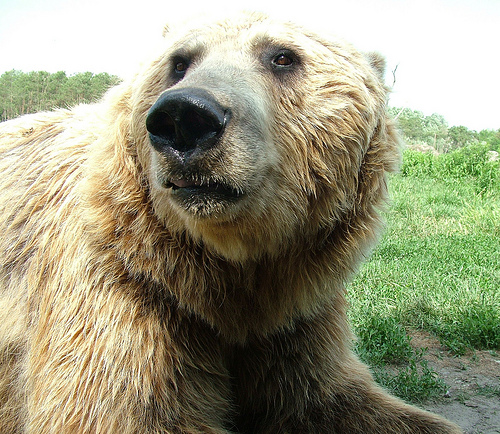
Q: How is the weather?
A: It is clear.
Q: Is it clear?
A: Yes, it is clear.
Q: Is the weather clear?
A: Yes, it is clear.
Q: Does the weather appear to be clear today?
A: Yes, it is clear.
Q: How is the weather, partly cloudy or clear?
A: It is clear.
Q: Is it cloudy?
A: No, it is clear.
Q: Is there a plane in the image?
A: No, there are no airplanes.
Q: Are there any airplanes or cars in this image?
A: No, there are no airplanes or cars.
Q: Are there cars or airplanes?
A: No, there are no airplanes or cars.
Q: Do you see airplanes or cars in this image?
A: No, there are no airplanes or cars.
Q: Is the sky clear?
A: Yes, the sky is clear.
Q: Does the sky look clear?
A: Yes, the sky is clear.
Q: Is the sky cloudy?
A: No, the sky is clear.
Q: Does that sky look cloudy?
A: No, the sky is clear.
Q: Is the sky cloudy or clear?
A: The sky is clear.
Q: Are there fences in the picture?
A: No, there are no fences.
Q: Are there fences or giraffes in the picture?
A: No, there are no fences or giraffes.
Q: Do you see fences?
A: No, there are no fences.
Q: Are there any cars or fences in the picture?
A: No, there are no fences or cars.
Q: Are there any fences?
A: No, there are no fences.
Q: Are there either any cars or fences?
A: No, there are no fences or cars.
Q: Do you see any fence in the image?
A: No, there are no fences.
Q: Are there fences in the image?
A: No, there are no fences.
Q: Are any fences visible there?
A: No, there are no fences.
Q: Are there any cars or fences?
A: No, there are no fences or cars.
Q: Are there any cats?
A: No, there are no cats.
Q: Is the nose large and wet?
A: Yes, the nose is large and wet.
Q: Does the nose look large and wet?
A: Yes, the nose is large and wet.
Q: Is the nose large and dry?
A: No, the nose is large but wet.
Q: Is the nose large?
A: Yes, the nose is large.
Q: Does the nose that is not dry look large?
A: Yes, the nose is large.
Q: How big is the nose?
A: The nose is large.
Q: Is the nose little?
A: No, the nose is large.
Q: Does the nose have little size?
A: No, the nose is large.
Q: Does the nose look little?
A: No, the nose is large.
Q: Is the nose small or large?
A: The nose is large.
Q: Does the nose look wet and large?
A: Yes, the nose is wet and large.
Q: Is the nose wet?
A: Yes, the nose is wet.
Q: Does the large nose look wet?
A: Yes, the nose is wet.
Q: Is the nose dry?
A: No, the nose is wet.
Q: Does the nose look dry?
A: No, the nose is wet.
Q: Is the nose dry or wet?
A: The nose is wet.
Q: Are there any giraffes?
A: No, there are no giraffes.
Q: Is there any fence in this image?
A: No, there are no fences.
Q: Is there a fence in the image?
A: No, there are no fences.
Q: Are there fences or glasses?
A: No, there are no fences or glasses.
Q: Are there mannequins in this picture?
A: No, there are no mannequins.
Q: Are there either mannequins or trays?
A: No, there are no mannequins or trays.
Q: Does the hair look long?
A: Yes, the hair is long.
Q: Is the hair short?
A: No, the hair is long.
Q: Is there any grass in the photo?
A: Yes, there is grass.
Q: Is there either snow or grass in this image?
A: Yes, there is grass.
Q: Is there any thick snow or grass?
A: Yes, there is thick grass.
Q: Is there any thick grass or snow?
A: Yes, there is thick grass.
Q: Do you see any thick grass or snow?
A: Yes, there is thick grass.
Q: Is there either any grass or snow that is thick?
A: Yes, the grass is thick.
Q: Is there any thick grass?
A: Yes, there is thick grass.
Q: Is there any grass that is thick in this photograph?
A: Yes, there is thick grass.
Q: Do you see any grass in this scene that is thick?
A: Yes, there is grass that is thick.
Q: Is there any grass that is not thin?
A: Yes, there is thick grass.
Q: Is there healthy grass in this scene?
A: Yes, there is healthy grass.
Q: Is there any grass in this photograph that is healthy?
A: Yes, there is grass that is healthy.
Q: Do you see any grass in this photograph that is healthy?
A: Yes, there is grass that is healthy.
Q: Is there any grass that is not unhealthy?
A: Yes, there is healthy grass.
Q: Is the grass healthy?
A: Yes, the grass is healthy.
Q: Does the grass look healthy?
A: Yes, the grass is healthy.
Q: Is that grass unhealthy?
A: No, the grass is healthy.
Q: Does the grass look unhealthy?
A: No, the grass is healthy.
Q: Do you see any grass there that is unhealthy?
A: No, there is grass but it is healthy.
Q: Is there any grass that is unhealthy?
A: No, there is grass but it is healthy.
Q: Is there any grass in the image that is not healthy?
A: No, there is grass but it is healthy.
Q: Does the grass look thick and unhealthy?
A: No, the grass is thick but healthy.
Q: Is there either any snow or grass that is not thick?
A: No, there is grass but it is thick.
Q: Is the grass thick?
A: Yes, the grass is thick.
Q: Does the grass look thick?
A: Yes, the grass is thick.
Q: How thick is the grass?
A: The grass is thick.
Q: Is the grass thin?
A: No, the grass is thick.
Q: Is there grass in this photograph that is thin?
A: No, there is grass but it is thick.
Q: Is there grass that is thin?
A: No, there is grass but it is thick.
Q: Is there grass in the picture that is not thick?
A: No, there is grass but it is thick.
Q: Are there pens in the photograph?
A: No, there are no pens.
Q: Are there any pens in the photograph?
A: No, there are no pens.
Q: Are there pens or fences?
A: No, there are no pens or fences.